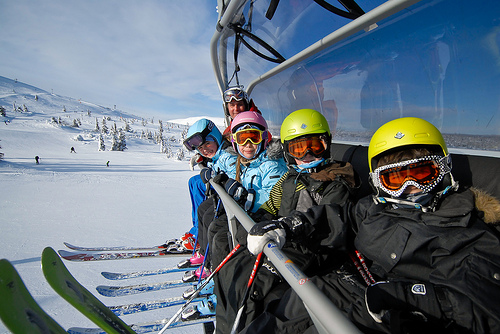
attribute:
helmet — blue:
[187, 121, 220, 143]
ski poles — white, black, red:
[60, 242, 174, 259]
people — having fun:
[142, 99, 499, 311]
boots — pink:
[154, 219, 222, 329]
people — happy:
[171, 85, 454, 327]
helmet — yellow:
[347, 100, 464, 196]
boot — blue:
[198, 276, 219, 327]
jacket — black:
[275, 169, 478, 332]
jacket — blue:
[231, 165, 279, 197]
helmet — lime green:
[278, 99, 337, 149]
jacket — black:
[371, 214, 484, 304]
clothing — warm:
[204, 152, 498, 322]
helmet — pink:
[220, 104, 265, 134]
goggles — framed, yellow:
[234, 129, 261, 143]